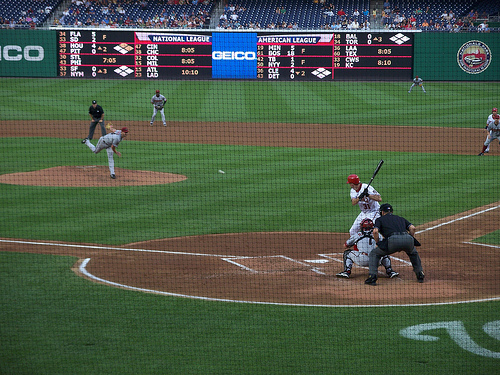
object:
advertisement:
[208, 27, 260, 81]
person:
[77, 121, 129, 181]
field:
[4, 74, 493, 367]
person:
[355, 199, 427, 287]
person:
[342, 171, 387, 251]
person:
[144, 87, 169, 127]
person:
[405, 71, 427, 95]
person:
[475, 103, 498, 155]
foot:
[81, 135, 87, 143]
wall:
[2, 26, 497, 78]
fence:
[212, 50, 256, 60]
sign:
[216, 48, 257, 68]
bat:
[353, 158, 386, 195]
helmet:
[345, 176, 362, 185]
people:
[4, 4, 494, 33]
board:
[60, 27, 411, 83]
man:
[84, 86, 112, 160]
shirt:
[92, 107, 105, 121]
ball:
[215, 168, 224, 178]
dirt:
[9, 118, 495, 303]